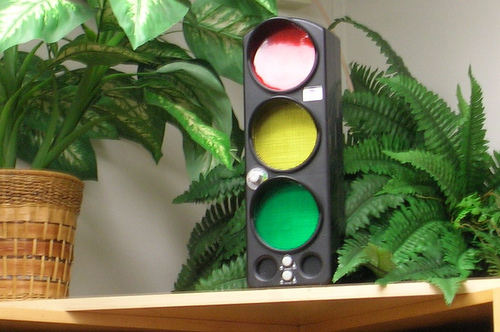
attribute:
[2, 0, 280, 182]
plant — green, leafy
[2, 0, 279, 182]
leaves — big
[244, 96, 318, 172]
sign — yellow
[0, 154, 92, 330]
pot — brown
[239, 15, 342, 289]
sign — red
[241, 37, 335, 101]
reflection — bright white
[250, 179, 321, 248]
part — green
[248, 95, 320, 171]
light — traffic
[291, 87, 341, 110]
sticker — small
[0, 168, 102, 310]
basket — wicker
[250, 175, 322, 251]
sign — green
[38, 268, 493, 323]
table — traffic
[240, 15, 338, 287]
light — traffic, plastic, fake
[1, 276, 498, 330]
shelf — brown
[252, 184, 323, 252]
light — green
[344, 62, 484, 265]
plant — green, leafy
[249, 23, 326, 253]
lights — red, yellow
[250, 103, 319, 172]
lens — yellow, plastic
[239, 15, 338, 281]
traffic light — fake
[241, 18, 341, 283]
replica — black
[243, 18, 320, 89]
shade — red